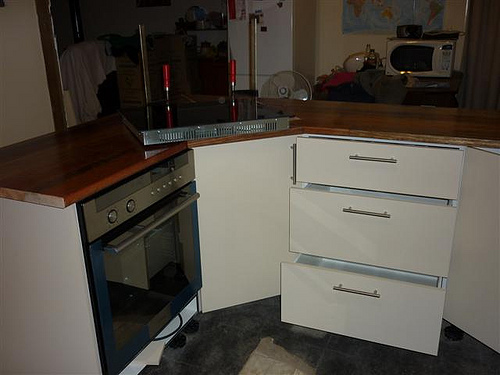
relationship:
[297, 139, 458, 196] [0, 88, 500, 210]
drawer under counter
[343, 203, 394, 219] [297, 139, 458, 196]
handle on drawer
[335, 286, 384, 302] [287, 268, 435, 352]
handle on drawer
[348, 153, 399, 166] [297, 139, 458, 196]
handle ` on drawer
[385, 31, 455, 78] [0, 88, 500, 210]
microwave in front of counter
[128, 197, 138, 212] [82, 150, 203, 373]
button on oven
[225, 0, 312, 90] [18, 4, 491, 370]
refrdgerator in kitchen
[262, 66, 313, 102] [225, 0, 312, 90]
fan in front of refrdgerator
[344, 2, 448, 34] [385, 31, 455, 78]
map above microwave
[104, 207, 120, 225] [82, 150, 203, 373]
button on oven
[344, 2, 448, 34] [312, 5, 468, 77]
map on wall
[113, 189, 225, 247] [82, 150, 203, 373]
handle ` on oven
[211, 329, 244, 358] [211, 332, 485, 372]
tile on floor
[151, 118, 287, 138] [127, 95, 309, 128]
grate on stove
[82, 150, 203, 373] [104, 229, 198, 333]
oven has door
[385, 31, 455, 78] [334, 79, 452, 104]
microwave on table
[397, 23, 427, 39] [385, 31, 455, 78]
pot on microwave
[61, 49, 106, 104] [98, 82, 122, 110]
sheet over furniture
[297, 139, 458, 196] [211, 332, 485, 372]
drawer above floor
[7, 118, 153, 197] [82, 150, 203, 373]
counter over oven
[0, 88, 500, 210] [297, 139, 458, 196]
counter over drawer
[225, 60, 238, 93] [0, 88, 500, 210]
handle behind counter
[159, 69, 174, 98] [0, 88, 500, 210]
handle behind counter